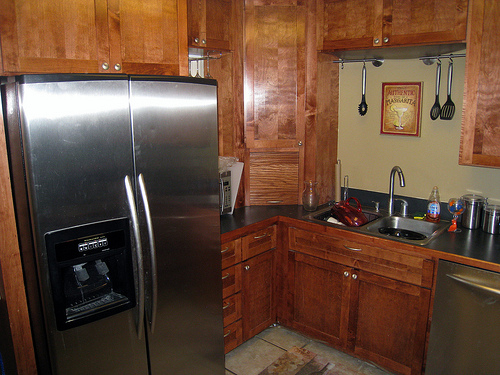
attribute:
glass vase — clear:
[298, 178, 318, 210]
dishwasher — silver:
[421, 256, 498, 374]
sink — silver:
[359, 162, 448, 247]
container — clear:
[422, 187, 445, 229]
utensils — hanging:
[333, 48, 463, 127]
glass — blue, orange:
[444, 193, 468, 236]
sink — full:
[316, 187, 446, 247]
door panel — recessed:
[2, 73, 152, 373]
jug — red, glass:
[332, 196, 368, 227]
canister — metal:
[482, 202, 496, 234]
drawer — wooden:
[289, 226, 434, 288]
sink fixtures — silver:
[370, 155, 412, 219]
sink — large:
[310, 163, 450, 243]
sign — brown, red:
[380, 85, 419, 138]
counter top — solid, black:
[220, 190, 498, 273]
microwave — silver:
[202, 156, 276, 216]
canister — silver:
[459, 191, 481, 235]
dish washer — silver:
[434, 267, 481, 370]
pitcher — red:
[330, 192, 368, 228]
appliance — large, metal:
[1, 68, 230, 373]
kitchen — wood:
[1, 2, 497, 372]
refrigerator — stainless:
[6, 67, 240, 373]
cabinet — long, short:
[239, 7, 309, 208]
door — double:
[126, 74, 226, 374]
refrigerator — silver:
[1, 72, 223, 341]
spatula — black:
[428, 60, 457, 120]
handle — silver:
[444, 62, 456, 95]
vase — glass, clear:
[299, 177, 323, 214]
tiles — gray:
[224, 323, 403, 373]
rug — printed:
[263, 343, 339, 371]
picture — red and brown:
[373, 80, 426, 145]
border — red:
[329, 193, 369, 221]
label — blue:
[425, 200, 446, 216]